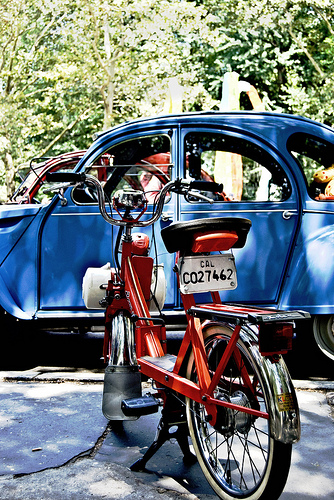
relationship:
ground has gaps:
[0, 364, 332, 499] [130, 463, 150, 472]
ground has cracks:
[0, 364, 332, 499] [54, 433, 126, 469]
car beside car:
[5, 151, 228, 210] [2, 109, 332, 377]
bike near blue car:
[36, 137, 299, 495] [3, 87, 333, 369]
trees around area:
[0, 0, 326, 219] [0, 106, 321, 497]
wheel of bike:
[183, 329, 296, 498] [44, 170, 308, 497]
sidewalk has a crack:
[0, 367, 332, 496] [13, 419, 111, 480]